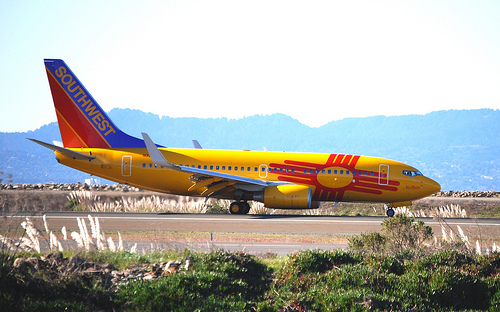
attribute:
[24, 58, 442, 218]
plane — large, yellow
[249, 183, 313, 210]
engine — yellow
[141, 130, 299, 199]
wing — silver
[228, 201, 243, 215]
wheel — black, small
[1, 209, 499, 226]
runway — long